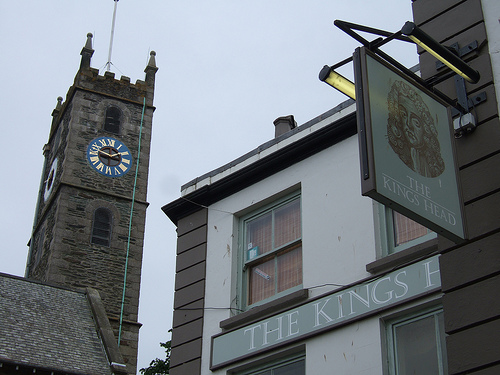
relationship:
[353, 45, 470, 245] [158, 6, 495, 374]
sign on front of building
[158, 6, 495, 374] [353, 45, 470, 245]
building has a big sign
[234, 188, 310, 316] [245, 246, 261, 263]
window has a label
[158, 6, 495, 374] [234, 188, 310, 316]
building has window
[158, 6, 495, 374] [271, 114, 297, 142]
building has a chimney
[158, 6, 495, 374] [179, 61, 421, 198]
building has gray edge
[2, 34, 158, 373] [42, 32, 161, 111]
building has spirals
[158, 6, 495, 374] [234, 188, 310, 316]
building has a window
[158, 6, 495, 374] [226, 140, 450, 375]
building has windows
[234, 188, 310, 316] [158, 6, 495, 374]
window on a building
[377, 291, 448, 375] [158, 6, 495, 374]
window on a building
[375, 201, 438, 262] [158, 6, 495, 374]
window on a building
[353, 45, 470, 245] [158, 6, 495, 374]
sign hanging on building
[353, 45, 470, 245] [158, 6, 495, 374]
sign on building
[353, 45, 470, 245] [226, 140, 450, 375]
sign between windows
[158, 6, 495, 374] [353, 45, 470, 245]
king's head has a sign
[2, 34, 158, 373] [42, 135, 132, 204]
building has clocks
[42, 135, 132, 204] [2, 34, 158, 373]
clocks on side of building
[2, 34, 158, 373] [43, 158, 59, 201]
building has a clock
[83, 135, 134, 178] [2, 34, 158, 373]
clock on side of building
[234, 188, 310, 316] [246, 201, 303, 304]
window has blinds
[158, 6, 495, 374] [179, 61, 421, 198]
building has a white roof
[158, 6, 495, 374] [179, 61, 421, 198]
building has a roof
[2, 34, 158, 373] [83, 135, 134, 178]
tower has a clock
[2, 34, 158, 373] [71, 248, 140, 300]
tower made of bricks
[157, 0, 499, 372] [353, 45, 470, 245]
store has a sign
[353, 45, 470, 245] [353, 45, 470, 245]
sign has sides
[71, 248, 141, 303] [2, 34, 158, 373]
bricks make tower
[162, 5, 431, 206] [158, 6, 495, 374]
sky above building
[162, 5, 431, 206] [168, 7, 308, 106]
sky above blue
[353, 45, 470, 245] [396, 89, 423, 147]
sign has a face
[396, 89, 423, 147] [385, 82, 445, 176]
face of a man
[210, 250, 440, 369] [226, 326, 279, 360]
banner has a part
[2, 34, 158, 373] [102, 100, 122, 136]
building has a window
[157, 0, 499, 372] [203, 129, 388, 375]
wall has white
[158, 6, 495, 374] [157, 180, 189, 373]
house has an edge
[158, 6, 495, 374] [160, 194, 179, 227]
building has a tip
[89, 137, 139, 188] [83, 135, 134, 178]
roman numerals on clock face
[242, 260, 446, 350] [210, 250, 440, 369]
words on sign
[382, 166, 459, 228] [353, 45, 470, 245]
words on sign